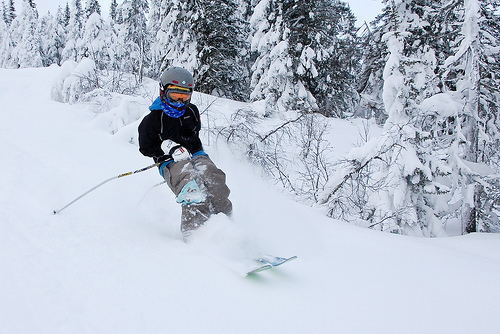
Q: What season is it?
A: Winter.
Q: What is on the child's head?
A: Helmet.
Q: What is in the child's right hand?
A: Ski pole.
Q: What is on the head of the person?
A: Helmet.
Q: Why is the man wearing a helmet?
A: For protection.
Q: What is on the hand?
A: A glove.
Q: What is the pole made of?
A: Metal.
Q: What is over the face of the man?
A: A blue scarf.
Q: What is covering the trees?
A: Snow.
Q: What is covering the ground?
A: Snow.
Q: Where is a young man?
A: On the snow.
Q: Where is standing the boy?
A: On the skies.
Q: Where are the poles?
A: Behind the boy.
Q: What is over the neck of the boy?
A: A scarf.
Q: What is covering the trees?
A: White snow.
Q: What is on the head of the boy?
A: A helmet.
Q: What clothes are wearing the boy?
A: Winter cloths.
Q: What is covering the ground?
A: Snow.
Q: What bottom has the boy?
A: Gray bottom.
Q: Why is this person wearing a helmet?
A: They're skiing.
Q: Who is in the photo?
A: A skier.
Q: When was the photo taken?
A: Daytime.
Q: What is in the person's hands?
A: Ski poles.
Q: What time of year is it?
A: Winter.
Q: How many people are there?
A: One.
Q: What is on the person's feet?
A: Skis.